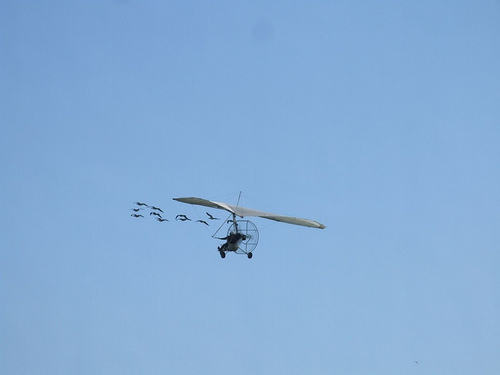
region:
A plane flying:
[128, 155, 323, 277]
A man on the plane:
[217, 227, 258, 256]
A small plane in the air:
[124, 162, 343, 304]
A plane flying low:
[117, 136, 372, 282]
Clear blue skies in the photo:
[353, 110, 438, 191]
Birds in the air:
[125, 186, 170, 228]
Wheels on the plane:
[228, 248, 273, 268]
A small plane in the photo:
[140, 165, 340, 291]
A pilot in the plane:
[216, 225, 249, 251]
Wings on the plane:
[255, 204, 322, 238]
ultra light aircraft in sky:
[164, 180, 329, 271]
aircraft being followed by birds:
[117, 185, 329, 268]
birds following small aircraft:
[125, 195, 223, 230]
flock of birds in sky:
[127, 198, 222, 231]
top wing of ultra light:
[167, 192, 332, 231]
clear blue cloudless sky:
[2, 2, 498, 374]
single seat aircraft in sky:
[170, 185, 337, 266]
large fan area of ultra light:
[224, 216, 264, 255]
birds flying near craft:
[120, 193, 225, 231]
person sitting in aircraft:
[212, 226, 247, 256]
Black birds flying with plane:
[131, 201, 218, 228]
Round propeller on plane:
[225, 220, 260, 255]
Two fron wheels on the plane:
[219, 246, 254, 261]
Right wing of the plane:
[250, 206, 330, 231]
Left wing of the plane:
[168, 193, 225, 215]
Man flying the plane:
[210, 223, 235, 241]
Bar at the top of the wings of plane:
[232, 187, 244, 207]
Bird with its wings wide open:
[204, 211, 219, 223]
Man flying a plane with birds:
[126, 184, 328, 269]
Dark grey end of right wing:
[312, 218, 326, 235]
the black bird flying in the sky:
[130, 212, 145, 223]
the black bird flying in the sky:
[130, 206, 140, 213]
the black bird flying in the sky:
[133, 198, 147, 208]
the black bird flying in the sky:
[148, 202, 160, 213]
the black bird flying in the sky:
[148, 211, 162, 217]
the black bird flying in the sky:
[155, 215, 167, 227]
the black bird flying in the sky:
[175, 212, 187, 219]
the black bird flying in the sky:
[177, 216, 187, 222]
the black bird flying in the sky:
[192, 217, 208, 227]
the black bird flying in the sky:
[205, 210, 220, 220]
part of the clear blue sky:
[428, 300, 487, 367]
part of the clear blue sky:
[331, 300, 393, 372]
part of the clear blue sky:
[218, 280, 290, 374]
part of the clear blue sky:
[130, 270, 212, 371]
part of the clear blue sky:
[15, 265, 107, 370]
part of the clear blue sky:
[418, 172, 473, 238]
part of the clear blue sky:
[307, 147, 361, 198]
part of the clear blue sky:
[27, 135, 88, 192]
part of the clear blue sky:
[173, 34, 256, 131]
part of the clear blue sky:
[8, 23, 59, 53]